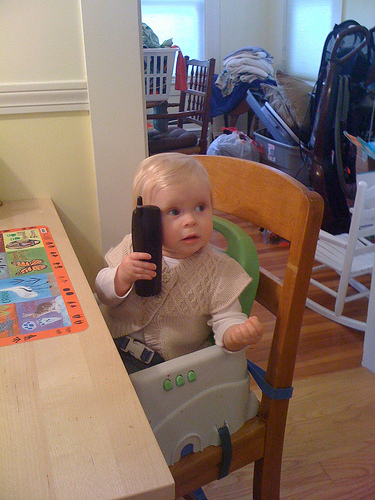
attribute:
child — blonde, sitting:
[115, 147, 243, 350]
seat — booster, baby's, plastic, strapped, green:
[125, 341, 273, 465]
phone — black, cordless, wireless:
[126, 201, 163, 304]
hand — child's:
[118, 252, 157, 284]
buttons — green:
[153, 361, 205, 397]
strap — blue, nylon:
[252, 363, 296, 405]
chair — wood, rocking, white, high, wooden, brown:
[143, 171, 296, 499]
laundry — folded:
[128, 16, 172, 51]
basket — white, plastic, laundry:
[127, 48, 180, 96]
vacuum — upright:
[308, 22, 374, 222]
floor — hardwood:
[252, 246, 372, 462]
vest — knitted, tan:
[124, 254, 228, 342]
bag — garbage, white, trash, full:
[200, 128, 272, 163]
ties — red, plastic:
[222, 121, 270, 148]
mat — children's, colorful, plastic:
[2, 224, 83, 347]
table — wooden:
[3, 178, 156, 500]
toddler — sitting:
[103, 161, 241, 347]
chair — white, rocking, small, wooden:
[297, 157, 373, 310]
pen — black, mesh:
[310, 18, 374, 206]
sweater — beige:
[122, 254, 227, 338]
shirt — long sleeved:
[98, 263, 263, 350]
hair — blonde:
[134, 155, 211, 184]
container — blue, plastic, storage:
[249, 117, 307, 181]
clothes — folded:
[220, 43, 278, 87]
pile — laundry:
[224, 47, 273, 87]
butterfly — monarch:
[16, 256, 44, 277]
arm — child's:
[93, 238, 132, 305]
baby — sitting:
[114, 157, 259, 358]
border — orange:
[44, 226, 87, 325]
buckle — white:
[125, 328, 155, 372]